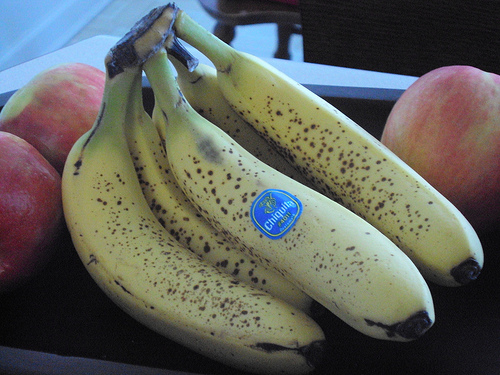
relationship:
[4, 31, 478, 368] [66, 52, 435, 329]
bin has fruit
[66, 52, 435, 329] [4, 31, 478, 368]
fruit in bin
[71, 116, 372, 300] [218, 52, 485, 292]
spots on banana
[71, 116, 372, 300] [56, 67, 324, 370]
spots on banana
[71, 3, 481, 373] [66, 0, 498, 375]
bunch has banana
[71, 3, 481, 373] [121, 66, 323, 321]
bunch has bananas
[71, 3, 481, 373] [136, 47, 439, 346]
bunch has bananas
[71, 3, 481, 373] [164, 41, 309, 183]
bunch has bananas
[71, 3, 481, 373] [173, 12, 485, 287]
bunch has bananas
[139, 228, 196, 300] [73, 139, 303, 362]
spots on banana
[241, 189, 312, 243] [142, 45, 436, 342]
label on banana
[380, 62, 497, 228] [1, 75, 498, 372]
orange in tray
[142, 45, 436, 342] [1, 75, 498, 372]
banana in tray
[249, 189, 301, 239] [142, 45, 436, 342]
sticker on banana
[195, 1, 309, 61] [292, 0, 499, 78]
chair at table